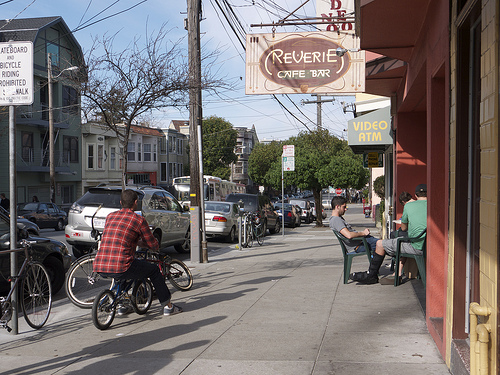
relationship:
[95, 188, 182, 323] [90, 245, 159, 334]
boy on bicycle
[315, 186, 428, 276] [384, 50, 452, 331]
guys at cafe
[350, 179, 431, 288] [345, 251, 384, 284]
man has cast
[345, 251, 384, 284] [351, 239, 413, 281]
cast on leg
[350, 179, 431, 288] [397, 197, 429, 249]
man wearing shirt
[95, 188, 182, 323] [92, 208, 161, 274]
boy wearing shirt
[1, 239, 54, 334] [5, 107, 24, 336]
bicycle next to pole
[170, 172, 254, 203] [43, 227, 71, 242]
bus on road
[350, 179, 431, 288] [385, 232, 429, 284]
man on chair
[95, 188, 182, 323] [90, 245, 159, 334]
boy riding bicycle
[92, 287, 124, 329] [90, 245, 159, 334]
wheel of bicycle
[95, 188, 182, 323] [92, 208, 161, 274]
boy in shirt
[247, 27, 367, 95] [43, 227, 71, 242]
sign above road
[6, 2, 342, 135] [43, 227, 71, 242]
sky above road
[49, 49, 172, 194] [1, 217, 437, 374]
tree on sidewalk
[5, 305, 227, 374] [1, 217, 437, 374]
shadow on sidewalk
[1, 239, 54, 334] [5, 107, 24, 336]
bicycle leaning on pole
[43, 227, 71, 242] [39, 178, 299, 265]
road full of cars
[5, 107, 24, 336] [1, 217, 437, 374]
pole on sidewalk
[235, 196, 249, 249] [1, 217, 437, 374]
parking meter on sidewalk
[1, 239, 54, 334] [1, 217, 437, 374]
bicycle on sidewalk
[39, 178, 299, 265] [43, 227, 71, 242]
cars on road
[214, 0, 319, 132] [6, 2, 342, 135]
wires in sky